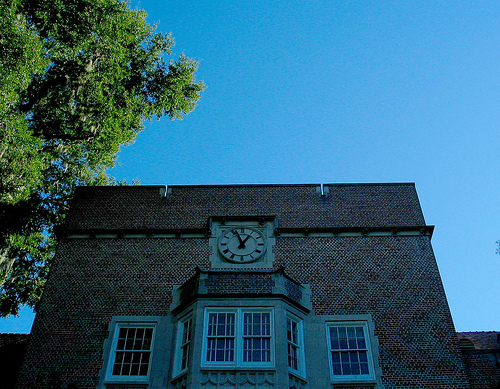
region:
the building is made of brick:
[352, 282, 367, 294]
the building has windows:
[101, 293, 385, 385]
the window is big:
[203, 299, 274, 369]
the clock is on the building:
[205, 210, 285, 275]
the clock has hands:
[227, 227, 255, 249]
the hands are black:
[232, 227, 252, 250]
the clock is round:
[215, 225, 268, 267]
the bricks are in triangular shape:
[380, 272, 441, 354]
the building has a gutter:
[297, 217, 449, 244]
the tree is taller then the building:
[26, 22, 200, 139]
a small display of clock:
[200, 205, 307, 287]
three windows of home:
[94, 308, 401, 386]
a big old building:
[42, 173, 470, 383]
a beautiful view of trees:
[3, 8, 193, 353]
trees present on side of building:
[2, 7, 164, 289]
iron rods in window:
[203, 312, 235, 381]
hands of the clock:
[225, 222, 252, 257]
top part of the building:
[66, 175, 448, 214]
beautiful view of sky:
[118, 5, 488, 150]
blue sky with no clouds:
[91, 25, 498, 200]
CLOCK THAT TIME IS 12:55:
[210, 216, 276, 267]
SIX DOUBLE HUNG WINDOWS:
[104, 302, 388, 386]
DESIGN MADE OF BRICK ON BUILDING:
[313, 249, 370, 304]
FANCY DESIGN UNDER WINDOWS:
[178, 369, 315, 387]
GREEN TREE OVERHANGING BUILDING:
[28, 51, 207, 207]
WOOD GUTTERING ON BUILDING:
[57, 217, 442, 244]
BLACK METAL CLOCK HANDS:
[229, 226, 257, 253]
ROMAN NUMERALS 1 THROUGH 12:
[215, 222, 272, 264]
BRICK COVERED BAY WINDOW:
[161, 267, 316, 387]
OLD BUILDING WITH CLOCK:
[3, 182, 498, 381]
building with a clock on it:
[47, 154, 461, 386]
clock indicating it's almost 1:
[203, 209, 291, 276]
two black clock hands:
[234, 227, 249, 250]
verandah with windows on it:
[168, 303, 322, 387]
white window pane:
[333, 368, 379, 385]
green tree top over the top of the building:
[1, 1, 232, 329]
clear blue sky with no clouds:
[106, 1, 496, 231]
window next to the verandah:
[303, 324, 373, 380]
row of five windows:
[101, 304, 403, 387]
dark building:
[23, 168, 474, 387]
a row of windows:
[102, 312, 387, 380]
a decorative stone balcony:
[154, 262, 329, 308]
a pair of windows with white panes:
[200, 300, 281, 370]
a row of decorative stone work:
[172, 363, 285, 387]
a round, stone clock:
[205, 212, 289, 273]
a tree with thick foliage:
[0, 88, 177, 291]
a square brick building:
[31, 152, 475, 387]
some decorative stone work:
[363, 235, 453, 369]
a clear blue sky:
[58, 76, 475, 228]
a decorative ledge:
[52, 214, 434, 239]